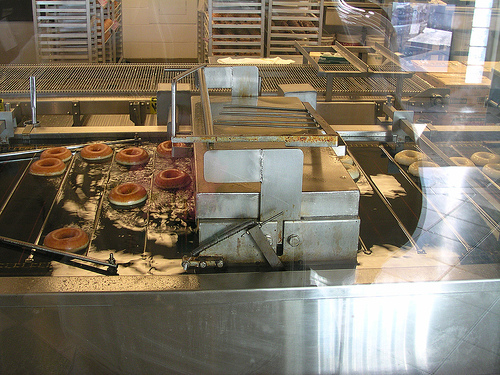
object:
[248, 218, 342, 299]
donut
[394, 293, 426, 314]
steel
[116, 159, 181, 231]
doughnut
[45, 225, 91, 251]
doughnut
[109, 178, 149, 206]
doughnut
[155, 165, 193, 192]
doughnut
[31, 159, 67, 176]
doughnut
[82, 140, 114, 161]
doughnut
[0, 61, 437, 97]
conveyor belt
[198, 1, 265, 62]
bakers rack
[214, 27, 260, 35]
donuts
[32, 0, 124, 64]
bakers rack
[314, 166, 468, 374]
reflection